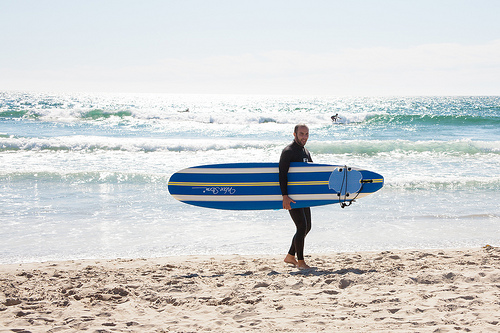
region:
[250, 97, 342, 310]
a man in the ground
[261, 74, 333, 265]
a man in the sand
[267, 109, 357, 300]
a man in the earth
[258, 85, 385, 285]
a man near the water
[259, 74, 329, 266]
a man near the sea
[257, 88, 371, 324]
a man near the beach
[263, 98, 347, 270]
a man near the ocean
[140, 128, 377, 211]
a man holding board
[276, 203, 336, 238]
legs of the person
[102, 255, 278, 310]
foot marks in the sand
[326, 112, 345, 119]
a person surfing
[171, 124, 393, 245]
a man carrying a surf board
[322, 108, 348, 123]
a surfer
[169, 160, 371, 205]
a blue and white surf board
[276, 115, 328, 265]
a man in a black wet suit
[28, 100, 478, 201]
waves in the water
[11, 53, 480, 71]
clouds in the sky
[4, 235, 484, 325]
the sand on the beach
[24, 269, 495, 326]
tracks in the sand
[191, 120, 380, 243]
a man standing on the beach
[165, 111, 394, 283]
man carrying surfboard in the sand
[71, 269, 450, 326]
sand on a beach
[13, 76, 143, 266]
water of an ocean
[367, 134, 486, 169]
waves in the ocean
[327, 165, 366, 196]
design on a surfboard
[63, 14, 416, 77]
blue sky in the distance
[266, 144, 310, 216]
arm holding a surfboard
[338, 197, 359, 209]
strap to a surfboard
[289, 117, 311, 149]
face of a surfer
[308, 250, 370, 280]
shadow in the sand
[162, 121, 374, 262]
a guy carrying a surfboard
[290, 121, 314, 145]
the head of a young man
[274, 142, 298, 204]
the arm of a young man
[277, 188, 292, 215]
the hand of a young man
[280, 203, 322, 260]
the legs of a young man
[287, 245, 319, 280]
the feet of a young man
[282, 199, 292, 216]
the fingers of a young man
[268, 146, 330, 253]
the wetsuit of a young man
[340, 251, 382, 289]
the shadow of a young man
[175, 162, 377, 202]
a large blue and white surfboard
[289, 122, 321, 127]
Man has short hair.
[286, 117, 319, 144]
Man has dark hair.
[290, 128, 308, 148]
Man has dark facial hair.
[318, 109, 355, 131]
Person surfing in water.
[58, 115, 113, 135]
Water is bright blue.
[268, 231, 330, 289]
Person walking on sandy beach.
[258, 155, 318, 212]
Person holding surfboard.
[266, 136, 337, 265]
Person wearing wet suit.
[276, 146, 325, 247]
Person's wet suit is black in color.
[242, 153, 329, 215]
Person carrying blue and white surfboard.